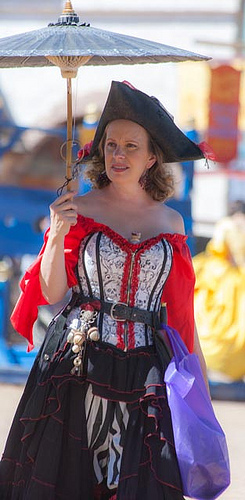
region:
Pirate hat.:
[71, 79, 213, 167]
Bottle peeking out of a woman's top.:
[128, 229, 140, 247]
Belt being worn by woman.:
[72, 290, 160, 325]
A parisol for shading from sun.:
[0, 0, 213, 225]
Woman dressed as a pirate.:
[1, 78, 216, 498]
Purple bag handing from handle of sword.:
[158, 301, 229, 498]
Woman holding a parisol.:
[0, 3, 215, 498]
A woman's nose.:
[112, 145, 124, 159]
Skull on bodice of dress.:
[103, 278, 120, 299]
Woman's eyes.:
[106, 139, 137, 149]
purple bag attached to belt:
[158, 325, 230, 498]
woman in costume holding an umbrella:
[0, 0, 243, 498]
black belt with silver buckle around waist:
[68, 293, 161, 329]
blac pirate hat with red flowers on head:
[74, 79, 219, 168]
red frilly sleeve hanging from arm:
[7, 256, 50, 353]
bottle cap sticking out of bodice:
[128, 230, 142, 246]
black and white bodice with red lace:
[62, 233, 172, 348]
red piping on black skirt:
[95, 390, 167, 404]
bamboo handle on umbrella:
[44, 55, 94, 192]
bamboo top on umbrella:
[60, 0, 75, 15]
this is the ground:
[220, 403, 235, 425]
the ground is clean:
[223, 416, 236, 425]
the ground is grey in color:
[225, 407, 234, 418]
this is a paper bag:
[175, 384, 199, 416]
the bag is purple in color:
[181, 401, 194, 417]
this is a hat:
[78, 87, 206, 158]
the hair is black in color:
[145, 116, 156, 125]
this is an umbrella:
[6, 15, 186, 62]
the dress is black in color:
[132, 440, 147, 460]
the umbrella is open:
[108, 35, 120, 45]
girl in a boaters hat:
[82, 74, 208, 192]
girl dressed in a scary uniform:
[5, 79, 217, 434]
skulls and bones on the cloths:
[120, 253, 160, 349]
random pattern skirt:
[20, 344, 234, 499]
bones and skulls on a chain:
[54, 296, 111, 382]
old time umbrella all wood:
[0, 17, 214, 230]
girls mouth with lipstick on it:
[103, 161, 138, 174]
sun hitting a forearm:
[23, 198, 72, 307]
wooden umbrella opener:
[45, 51, 100, 91]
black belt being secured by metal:
[94, 301, 154, 326]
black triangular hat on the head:
[88, 77, 209, 177]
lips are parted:
[106, 162, 131, 173]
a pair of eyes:
[106, 140, 139, 151]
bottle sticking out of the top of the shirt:
[127, 226, 144, 244]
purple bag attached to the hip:
[150, 322, 234, 498]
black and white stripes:
[78, 388, 133, 492]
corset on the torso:
[7, 209, 212, 373]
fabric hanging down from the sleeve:
[10, 272, 45, 356]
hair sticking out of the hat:
[144, 132, 182, 204]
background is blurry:
[0, 0, 244, 401]